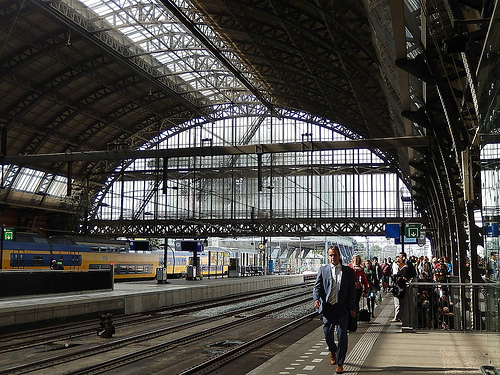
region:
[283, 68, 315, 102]
section of a roof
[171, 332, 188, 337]
section of a railway line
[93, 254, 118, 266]
section of a train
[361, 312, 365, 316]
part of a travelling bag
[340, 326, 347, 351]
left leg of a man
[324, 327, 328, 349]
right leg of a man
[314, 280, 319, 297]
right arm of a man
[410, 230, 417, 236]
section of a green sign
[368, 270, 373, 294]
a woman on the train station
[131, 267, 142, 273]
section of a train's window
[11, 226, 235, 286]
Yellow train in substation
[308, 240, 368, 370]
Man wearing a suit walking on the sidewalk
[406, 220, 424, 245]
Green sign with white arrow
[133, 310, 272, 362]
Sets of train tracks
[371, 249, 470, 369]
Subway loading platform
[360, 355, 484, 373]
Shadow from man walking on the sidewalk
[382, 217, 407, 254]
Blue flag hanging from a black pole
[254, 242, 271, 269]
Signal light for train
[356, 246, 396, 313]
Group of people walking on a sidewalk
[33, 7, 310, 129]
Sky lights on roof of train station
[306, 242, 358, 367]
man in suit walking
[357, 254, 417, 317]
crowd of people on platform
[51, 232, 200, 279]
yellow and blue train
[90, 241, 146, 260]
windows on commuter train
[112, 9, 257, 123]
skylights in station roof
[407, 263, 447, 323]
people in station strairwell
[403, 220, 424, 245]
sign with white arrow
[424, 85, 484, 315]
curved metal bars over station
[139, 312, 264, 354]
empty tracks in station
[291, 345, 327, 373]
white squares on platform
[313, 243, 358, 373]
a well dressed man walking on the platform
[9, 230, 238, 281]
a blue and yellow train waiting at the platform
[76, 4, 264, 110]
a long window in the domed ceiling of the station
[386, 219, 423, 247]
green and blue signs hanging above the platform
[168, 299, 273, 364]
several empty rail tracks at the station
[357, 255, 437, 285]
many people walking on the platform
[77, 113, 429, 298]
large windowed end of the domed station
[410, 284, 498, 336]
a barricade on the platform by some stairs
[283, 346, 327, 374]
white lines on the ground near the tracks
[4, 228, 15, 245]
a green sign on the other side of the station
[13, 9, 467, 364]
People are on a train platform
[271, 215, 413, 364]
A man is walking wearing a suit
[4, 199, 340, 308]
A train is in the photo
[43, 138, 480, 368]
Photo was taken during the day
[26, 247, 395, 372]
Train tracks are in the photo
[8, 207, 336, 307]
The train is yellow and blue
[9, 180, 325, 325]
Train is next to the platform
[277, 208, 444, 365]
A woman is behind the man in the suit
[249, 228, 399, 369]
The man's suit is blue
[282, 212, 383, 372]
The man is wearing brown shoes